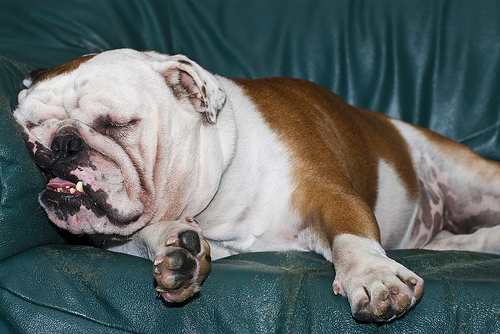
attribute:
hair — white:
[97, 57, 161, 99]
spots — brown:
[157, 53, 225, 125]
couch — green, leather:
[2, 2, 497, 332]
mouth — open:
[36, 171, 97, 206]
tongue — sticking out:
[46, 174, 78, 192]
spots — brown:
[177, 54, 215, 108]